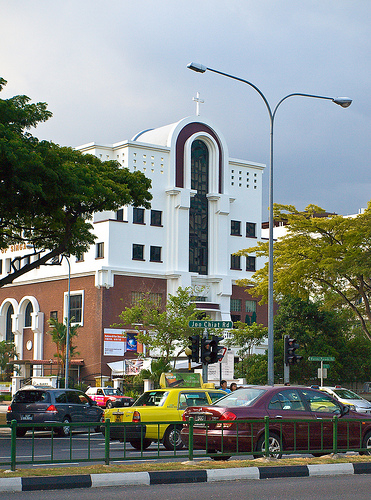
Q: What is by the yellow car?
A: Red car.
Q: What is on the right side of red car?
A: Green fence.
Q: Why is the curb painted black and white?
A: Parking.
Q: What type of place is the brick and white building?
A: Church.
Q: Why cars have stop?
A: Traffic signal.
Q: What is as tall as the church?
A: Light pole.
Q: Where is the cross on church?
A: Top.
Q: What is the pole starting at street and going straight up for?
A: Street lights.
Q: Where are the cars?
A: On the street.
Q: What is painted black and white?
A: The curb.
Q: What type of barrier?
A: A fence.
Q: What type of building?
A: Church.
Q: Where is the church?
A: Across the street.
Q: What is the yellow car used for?
A: Taxi.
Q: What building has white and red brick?
A: The church.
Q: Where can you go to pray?
A: The church.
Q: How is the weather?
A: Overcast.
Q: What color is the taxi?
A: Yellow.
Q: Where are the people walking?
A: Across the street.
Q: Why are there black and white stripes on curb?
A: Visibility.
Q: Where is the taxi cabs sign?
A: On car roof.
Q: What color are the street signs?
A: Green.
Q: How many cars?
A: Five.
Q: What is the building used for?
A: Church.